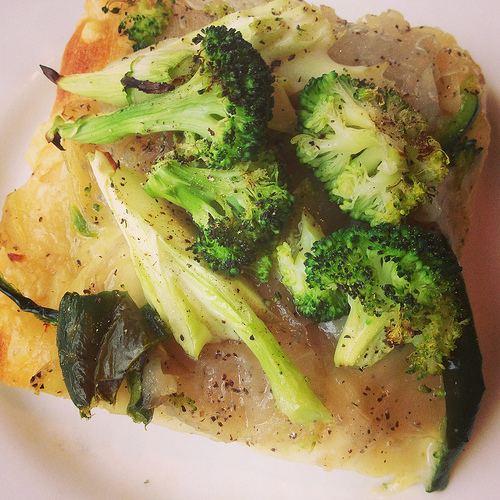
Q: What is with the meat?
A: Veggies.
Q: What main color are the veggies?
A: Green.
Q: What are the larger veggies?
A: Broccoli.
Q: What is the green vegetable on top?
A: Broccoli.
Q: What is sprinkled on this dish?
A: Pepper.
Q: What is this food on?
A: Plate.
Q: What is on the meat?
A: Spinach.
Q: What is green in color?
A: The stem.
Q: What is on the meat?
A: A pepper.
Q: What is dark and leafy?
A: Vegetable.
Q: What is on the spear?
A: Broccoli.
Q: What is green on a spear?
A: Broccoli.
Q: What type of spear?
A: Green.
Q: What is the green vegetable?
A: Broccoli.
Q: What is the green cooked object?
A: A leaf.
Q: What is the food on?
A: A white plate.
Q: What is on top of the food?
A: Seasoning.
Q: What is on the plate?
A: Pile of vegetables.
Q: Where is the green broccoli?
A: On top of the other food.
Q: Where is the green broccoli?
A: On the plate.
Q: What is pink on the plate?
A: The meat.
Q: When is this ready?
A: Now.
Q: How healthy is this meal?
A: Very healthy.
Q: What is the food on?
A: Plate.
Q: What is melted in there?
A: Cheese.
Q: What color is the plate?
A: White.